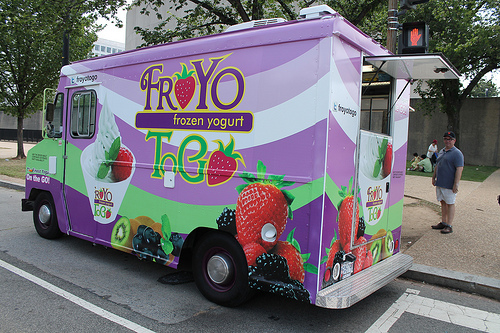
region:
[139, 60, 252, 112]
logo on the truck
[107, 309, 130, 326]
a white line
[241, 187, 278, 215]
a strawberry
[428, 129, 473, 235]
a man standing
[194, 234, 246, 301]
back tire of the truck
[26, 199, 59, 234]
front tire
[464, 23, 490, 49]
a bush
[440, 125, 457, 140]
man wearing a hat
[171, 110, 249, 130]
writing on the truck is yellow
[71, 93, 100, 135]
window on the truck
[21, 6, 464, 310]
Frozen yogurt to go, curbside truck.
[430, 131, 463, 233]
Man staring at the camera.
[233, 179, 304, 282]
Realistic strawberries painted on truck.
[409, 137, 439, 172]
Family group playing under tree.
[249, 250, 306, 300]
Realistic blackberries painted on truck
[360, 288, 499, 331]
Lines painted on road to delineate parking areas.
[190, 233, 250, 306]
Tire on yogurt truck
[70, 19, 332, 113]
Very nice shades of purple painted on truck.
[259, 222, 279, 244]
Gas filler cap in middle of strawberry.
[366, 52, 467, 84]
Open back overhead access door.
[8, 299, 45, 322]
Part of the street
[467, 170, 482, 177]
Part of the green grass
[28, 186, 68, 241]
The front tire of the truck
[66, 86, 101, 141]
A window on the truck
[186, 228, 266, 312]
The back tire of the truck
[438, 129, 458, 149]
The head of the person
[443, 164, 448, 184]
Part of the shirt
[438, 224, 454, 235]
The left foot of the person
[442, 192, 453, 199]
Part of the shorts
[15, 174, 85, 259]
wheel of a van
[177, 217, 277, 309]
wheel of a van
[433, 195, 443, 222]
leg of a person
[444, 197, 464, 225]
leg of a person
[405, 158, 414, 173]
leg of a person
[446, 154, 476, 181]
arm of a message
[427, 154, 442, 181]
arm of a message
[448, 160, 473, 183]
an arm of a message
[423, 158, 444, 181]
an arm of a message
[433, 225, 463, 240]
feet of a person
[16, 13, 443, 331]
purple froyo frozen yogurt truck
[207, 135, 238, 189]
strawberry on the truck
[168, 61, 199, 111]
strawberry on the truck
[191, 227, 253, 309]
tire on the truck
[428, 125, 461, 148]
hat on the mans head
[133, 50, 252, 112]
froyo on the truck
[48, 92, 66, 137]
window on the truck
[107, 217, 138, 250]
kiwi on the truck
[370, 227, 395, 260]
kiwi's on the truck